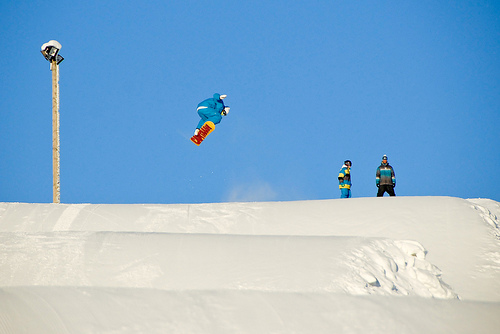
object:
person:
[193, 93, 232, 136]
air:
[236, 67, 282, 94]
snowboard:
[189, 121, 216, 147]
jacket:
[195, 92, 225, 114]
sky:
[104, 58, 137, 75]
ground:
[113, 224, 159, 252]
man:
[337, 159, 352, 199]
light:
[40, 39, 65, 64]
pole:
[51, 60, 61, 204]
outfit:
[195, 92, 231, 130]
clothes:
[375, 161, 396, 187]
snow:
[61, 239, 399, 278]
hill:
[24, 205, 457, 318]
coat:
[337, 164, 352, 189]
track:
[376, 247, 418, 299]